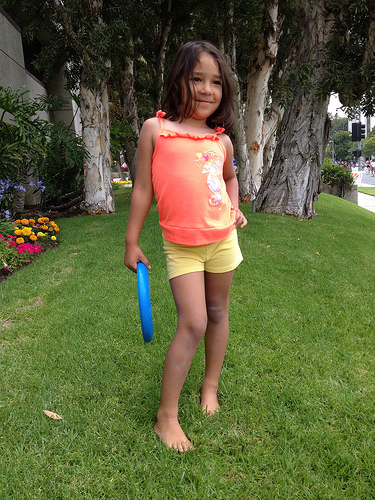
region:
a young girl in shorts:
[124, 38, 249, 456]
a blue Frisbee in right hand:
[132, 248, 161, 344]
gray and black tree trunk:
[261, 32, 355, 218]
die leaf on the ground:
[39, 408, 60, 429]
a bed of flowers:
[4, 211, 57, 280]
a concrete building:
[5, 16, 54, 178]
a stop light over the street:
[348, 116, 370, 143]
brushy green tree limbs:
[62, 0, 161, 96]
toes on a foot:
[150, 414, 198, 457]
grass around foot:
[196, 385, 227, 426]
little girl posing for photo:
[117, 38, 267, 457]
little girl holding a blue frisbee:
[98, 68, 272, 343]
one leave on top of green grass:
[25, 392, 68, 438]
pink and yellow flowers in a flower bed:
[8, 200, 62, 276]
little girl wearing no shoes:
[138, 364, 258, 450]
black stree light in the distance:
[342, 116, 374, 153]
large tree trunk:
[245, 6, 348, 205]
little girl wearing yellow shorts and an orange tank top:
[125, 107, 250, 296]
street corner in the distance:
[331, 112, 372, 189]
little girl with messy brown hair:
[144, 32, 254, 137]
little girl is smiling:
[108, 28, 266, 460]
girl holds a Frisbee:
[108, 36, 263, 462]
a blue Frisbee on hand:
[113, 222, 166, 361]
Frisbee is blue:
[128, 257, 164, 350]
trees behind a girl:
[30, 0, 361, 458]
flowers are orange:
[15, 206, 65, 234]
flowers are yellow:
[36, 230, 71, 246]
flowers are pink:
[17, 245, 43, 254]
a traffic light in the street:
[343, 107, 370, 149]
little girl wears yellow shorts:
[111, 29, 267, 460]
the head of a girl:
[159, 38, 228, 123]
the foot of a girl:
[152, 412, 200, 456]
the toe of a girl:
[176, 442, 185, 453]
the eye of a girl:
[189, 73, 206, 85]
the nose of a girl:
[197, 79, 213, 96]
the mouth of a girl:
[192, 95, 216, 105]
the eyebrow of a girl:
[187, 68, 205, 76]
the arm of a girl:
[122, 118, 158, 246]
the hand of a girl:
[121, 242, 153, 276]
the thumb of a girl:
[139, 251, 154, 269]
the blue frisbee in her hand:
[122, 243, 157, 342]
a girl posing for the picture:
[109, 33, 252, 459]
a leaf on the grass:
[36, 399, 63, 428]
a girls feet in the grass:
[149, 378, 228, 472]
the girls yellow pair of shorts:
[156, 225, 245, 285]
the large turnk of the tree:
[256, 165, 317, 220]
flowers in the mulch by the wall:
[0, 170, 59, 263]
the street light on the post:
[349, 117, 367, 148]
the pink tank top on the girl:
[147, 112, 237, 246]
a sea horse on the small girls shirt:
[199, 159, 226, 213]